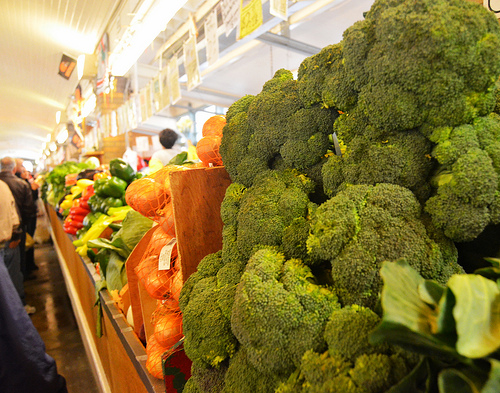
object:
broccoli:
[230, 248, 342, 375]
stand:
[38, 164, 234, 391]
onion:
[122, 176, 169, 217]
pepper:
[100, 175, 128, 197]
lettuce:
[118, 209, 153, 251]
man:
[0, 155, 35, 283]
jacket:
[0, 171, 35, 231]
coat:
[0, 179, 21, 242]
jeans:
[0, 247, 58, 387]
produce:
[34, 0, 499, 392]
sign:
[166, 58, 183, 107]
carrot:
[98, 226, 116, 241]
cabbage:
[93, 249, 128, 296]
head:
[0, 156, 19, 175]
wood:
[167, 165, 232, 285]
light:
[107, 0, 187, 77]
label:
[157, 236, 176, 270]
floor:
[26, 238, 99, 392]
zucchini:
[75, 179, 95, 191]